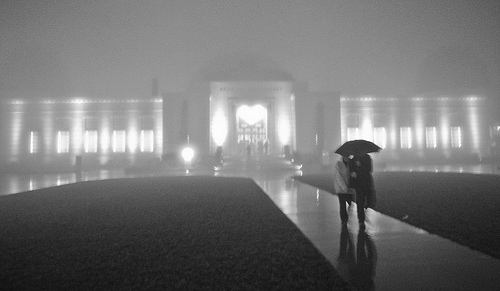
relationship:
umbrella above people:
[336, 137, 381, 158] [334, 153, 377, 230]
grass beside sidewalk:
[52, 183, 284, 281] [254, 176, 498, 271]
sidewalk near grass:
[254, 176, 498, 271] [52, 183, 284, 281]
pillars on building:
[183, 89, 216, 159] [23, 81, 494, 167]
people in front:
[334, 153, 377, 230] [197, 79, 327, 187]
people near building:
[334, 153, 377, 230] [23, 81, 494, 167]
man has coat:
[332, 154, 355, 228] [334, 159, 352, 196]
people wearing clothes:
[347, 153, 377, 230] [352, 157, 376, 204]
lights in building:
[236, 103, 266, 126] [23, 81, 494, 167]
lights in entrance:
[236, 103, 266, 126] [226, 98, 277, 151]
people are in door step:
[246, 140, 270, 156] [225, 152, 298, 171]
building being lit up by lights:
[6, 38, 496, 178] [6, 99, 496, 146]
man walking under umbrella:
[354, 148, 377, 234] [333, 134, 380, 164]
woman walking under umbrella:
[334, 150, 354, 226] [333, 134, 380, 164]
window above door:
[229, 96, 273, 136] [241, 122, 260, 148]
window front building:
[28, 128, 43, 153] [0, 93, 36, 172]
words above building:
[170, 48, 302, 106] [37, 46, 497, 208]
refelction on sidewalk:
[275, 186, 293, 214] [250, 174, 498, 289]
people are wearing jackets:
[347, 153, 377, 230] [334, 154, 384, 206]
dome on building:
[0, 40, 77, 97] [6, 38, 496, 178]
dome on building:
[192, 47, 289, 77] [6, 38, 496, 178]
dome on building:
[414, 43, 496, 95] [6, 38, 496, 178]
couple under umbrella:
[313, 152, 396, 217] [327, 123, 407, 160]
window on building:
[139, 127, 156, 152] [0, 93, 36, 172]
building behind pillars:
[0, 93, 36, 172] [2, 95, 497, 165]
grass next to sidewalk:
[0, 175, 347, 291] [251, 174, 498, 291]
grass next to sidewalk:
[290, 170, 499, 261] [251, 174, 498, 291]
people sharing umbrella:
[347, 153, 377, 230] [334, 135, 371, 155]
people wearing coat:
[347, 153, 377, 230] [335, 159, 356, 194]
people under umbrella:
[347, 153, 377, 230] [335, 140, 381, 156]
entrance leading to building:
[221, 96, 278, 151] [0, 93, 36, 172]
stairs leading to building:
[219, 153, 299, 174] [0, 93, 36, 172]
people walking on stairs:
[246, 140, 270, 156] [219, 153, 299, 174]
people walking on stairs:
[347, 153, 377, 230] [219, 153, 299, 174]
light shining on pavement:
[180, 147, 196, 166] [237, 166, 495, 288]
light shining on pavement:
[209, 100, 229, 148] [237, 166, 495, 288]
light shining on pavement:
[236, 101, 266, 124] [237, 166, 495, 288]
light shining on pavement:
[276, 107, 292, 146] [237, 166, 495, 288]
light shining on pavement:
[361, 114, 373, 143] [237, 166, 495, 288]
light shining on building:
[6, 100, 25, 163] [0, 93, 36, 172]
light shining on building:
[66, 96, 86, 165] [0, 93, 36, 172]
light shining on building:
[41, 100, 52, 157] [0, 93, 36, 172]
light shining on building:
[97, 113, 110, 162] [0, 93, 36, 172]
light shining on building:
[124, 119, 138, 155] [0, 93, 36, 172]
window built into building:
[28, 128, 43, 153] [0, 93, 36, 172]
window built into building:
[55, 128, 70, 153] [0, 93, 36, 172]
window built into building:
[81, 129, 100, 153] [0, 93, 36, 172]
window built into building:
[111, 128, 128, 154] [0, 93, 36, 172]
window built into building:
[139, 127, 156, 152] [0, 93, 36, 172]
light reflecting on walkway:
[1, 169, 22, 198] [2, 166, 131, 195]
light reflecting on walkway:
[27, 171, 35, 191] [2, 166, 131, 195]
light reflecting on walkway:
[54, 170, 62, 185] [2, 166, 131, 195]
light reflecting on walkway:
[84, 173, 89, 183] [2, 166, 131, 195]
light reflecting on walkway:
[97, 169, 108, 179] [2, 166, 131, 195]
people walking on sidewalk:
[347, 153, 377, 230] [251, 174, 498, 291]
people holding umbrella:
[347, 153, 377, 230] [345, 142, 382, 150]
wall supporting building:
[14, 100, 487, 164] [5, 49, 490, 180]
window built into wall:
[28, 130, 39, 155] [14, 100, 487, 164]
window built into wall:
[55, 128, 70, 153] [14, 100, 487, 164]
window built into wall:
[82, 130, 100, 152] [14, 100, 487, 164]